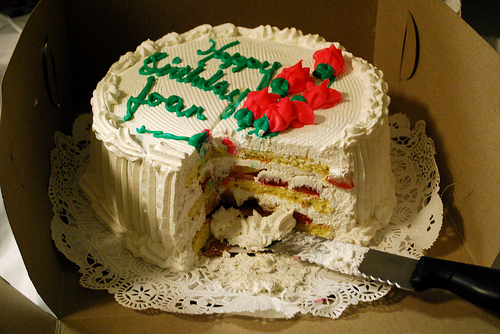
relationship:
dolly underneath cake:
[368, 118, 456, 275] [79, 18, 401, 283]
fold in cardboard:
[34, 36, 70, 115] [9, 7, 492, 330]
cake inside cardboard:
[79, 18, 401, 283] [9, 7, 492, 330]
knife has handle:
[272, 225, 499, 328] [414, 248, 496, 325]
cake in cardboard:
[79, 18, 401, 283] [9, 7, 492, 330]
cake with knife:
[79, 18, 401, 283] [272, 225, 499, 328]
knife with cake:
[272, 225, 499, 328] [79, 18, 401, 283]